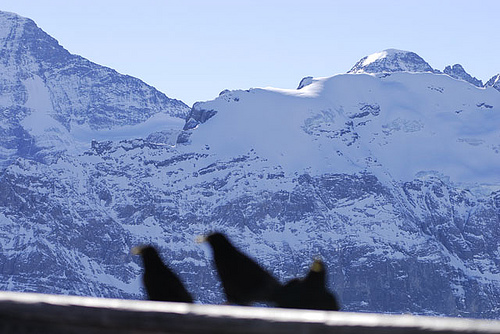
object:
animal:
[282, 261, 339, 310]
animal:
[129, 242, 194, 301]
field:
[1, 10, 499, 317]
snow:
[188, 70, 499, 195]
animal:
[194, 229, 286, 307]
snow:
[447, 84, 489, 112]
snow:
[338, 84, 426, 111]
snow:
[76, 100, 161, 128]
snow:
[11, 44, 67, 76]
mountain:
[2, 11, 493, 278]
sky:
[46, 1, 498, 103]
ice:
[239, 100, 480, 170]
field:
[0, 297, 498, 331]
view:
[417, 91, 486, 154]